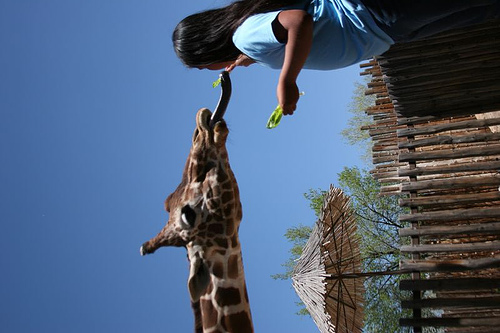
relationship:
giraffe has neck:
[139, 109, 276, 331] [181, 246, 256, 330]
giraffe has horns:
[139, 109, 276, 331] [135, 228, 172, 264]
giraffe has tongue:
[139, 109, 276, 331] [206, 70, 238, 127]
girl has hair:
[171, 4, 499, 117] [172, 0, 274, 71]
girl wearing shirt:
[171, 4, 499, 117] [232, 0, 404, 77]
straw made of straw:
[287, 189, 366, 333] [302, 273, 330, 297]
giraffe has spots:
[139, 109, 276, 331] [201, 286, 241, 327]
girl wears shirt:
[171, 4, 499, 117] [232, 0, 404, 77]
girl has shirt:
[171, 4, 499, 117] [232, 0, 404, 77]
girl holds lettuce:
[171, 4, 499, 117] [264, 107, 297, 133]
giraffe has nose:
[139, 109, 276, 331] [193, 124, 202, 151]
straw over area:
[287, 189, 366, 333] [364, 217, 473, 310]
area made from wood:
[359, 0, 500, 331] [401, 226, 499, 244]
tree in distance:
[341, 175, 407, 328] [253, 95, 469, 328]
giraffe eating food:
[139, 109, 276, 331] [211, 74, 225, 91]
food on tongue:
[211, 74, 225, 91] [206, 70, 238, 127]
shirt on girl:
[232, 0, 404, 77] [171, 4, 499, 117]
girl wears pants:
[171, 4, 499, 117] [362, 4, 499, 37]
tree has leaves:
[341, 175, 407, 328] [344, 169, 375, 205]